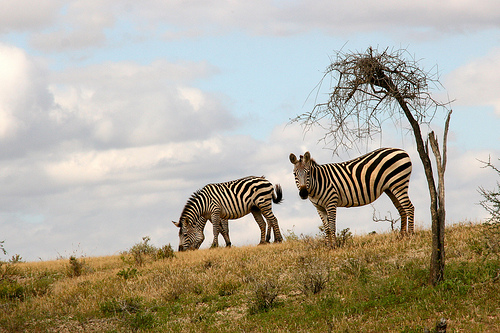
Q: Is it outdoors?
A: Yes, it is outdoors.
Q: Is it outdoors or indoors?
A: It is outdoors.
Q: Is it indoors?
A: No, it is outdoors.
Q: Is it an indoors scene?
A: No, it is outdoors.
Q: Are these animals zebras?
A: Yes, all the animals are zebras.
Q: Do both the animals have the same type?
A: Yes, all the animals are zebras.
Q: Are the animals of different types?
A: No, all the animals are zebras.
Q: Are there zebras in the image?
A: Yes, there is a zebra.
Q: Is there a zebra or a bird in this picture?
A: Yes, there is a zebra.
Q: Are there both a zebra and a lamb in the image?
A: No, there is a zebra but no lambs.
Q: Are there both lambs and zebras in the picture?
A: No, there is a zebra but no lambs.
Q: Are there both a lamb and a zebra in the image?
A: No, there is a zebra but no lambs.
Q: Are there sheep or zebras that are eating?
A: Yes, the zebra is eating.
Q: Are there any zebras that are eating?
A: Yes, there is a zebra that is eating.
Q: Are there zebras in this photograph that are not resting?
A: Yes, there is a zebra that is eating.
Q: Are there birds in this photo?
A: No, there are no birds.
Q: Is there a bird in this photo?
A: No, there are no birds.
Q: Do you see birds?
A: No, there are no birds.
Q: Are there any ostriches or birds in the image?
A: No, there are no birds or ostriches.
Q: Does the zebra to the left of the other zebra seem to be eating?
A: Yes, the zebra is eating.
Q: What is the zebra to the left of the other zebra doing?
A: The zebra is eating.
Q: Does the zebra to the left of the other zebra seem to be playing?
A: No, the zebra is eating.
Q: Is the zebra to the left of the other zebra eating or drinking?
A: The zebra is eating.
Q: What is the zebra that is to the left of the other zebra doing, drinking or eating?
A: The zebra is eating.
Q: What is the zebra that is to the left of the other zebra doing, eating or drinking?
A: The zebra is eating.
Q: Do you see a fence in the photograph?
A: No, there are no fences.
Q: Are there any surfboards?
A: No, there are no surfboards.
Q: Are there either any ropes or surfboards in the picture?
A: No, there are no surfboards or ropes.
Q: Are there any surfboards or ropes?
A: No, there are no surfboards or ropes.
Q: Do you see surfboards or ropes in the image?
A: No, there are no surfboards or ropes.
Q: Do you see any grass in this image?
A: Yes, there is grass.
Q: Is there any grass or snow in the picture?
A: Yes, there is grass.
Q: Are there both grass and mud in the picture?
A: No, there is grass but no mud.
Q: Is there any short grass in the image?
A: Yes, there is short grass.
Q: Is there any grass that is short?
A: Yes, there is grass that is short.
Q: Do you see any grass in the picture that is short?
A: Yes, there is grass that is short.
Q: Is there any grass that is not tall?
A: Yes, there is short grass.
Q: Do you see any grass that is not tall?
A: Yes, there is short grass.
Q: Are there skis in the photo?
A: No, there are no skis.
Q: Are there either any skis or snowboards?
A: No, there are no skis or snowboards.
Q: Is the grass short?
A: Yes, the grass is short.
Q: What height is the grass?
A: The grass is short.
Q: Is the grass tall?
A: No, the grass is short.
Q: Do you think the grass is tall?
A: No, the grass is short.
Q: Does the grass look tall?
A: No, the grass is short.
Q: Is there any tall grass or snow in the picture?
A: No, there is grass but it is short.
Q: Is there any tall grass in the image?
A: No, there is grass but it is short.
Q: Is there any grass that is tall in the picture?
A: No, there is grass but it is short.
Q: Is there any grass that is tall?
A: No, there is grass but it is short.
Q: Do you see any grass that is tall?
A: No, there is grass but it is short.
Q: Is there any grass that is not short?
A: No, there is grass but it is short.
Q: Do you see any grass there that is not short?
A: No, there is grass but it is short.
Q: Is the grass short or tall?
A: The grass is short.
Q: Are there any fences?
A: No, there are no fences.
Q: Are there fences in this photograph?
A: No, there are no fences.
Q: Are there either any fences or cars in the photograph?
A: No, there are no fences or cars.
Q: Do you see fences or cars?
A: No, there are no fences or cars.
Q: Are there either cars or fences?
A: No, there are no fences or cars.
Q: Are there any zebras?
A: Yes, there is a zebra.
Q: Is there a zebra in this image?
A: Yes, there is a zebra.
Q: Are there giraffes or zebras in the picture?
A: Yes, there is a zebra.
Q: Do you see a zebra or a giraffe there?
A: Yes, there is a zebra.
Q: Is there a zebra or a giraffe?
A: Yes, there is a zebra.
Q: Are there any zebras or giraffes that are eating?
A: Yes, the zebra is eating.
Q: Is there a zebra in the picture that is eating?
A: Yes, there is a zebra that is eating.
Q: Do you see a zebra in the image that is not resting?
A: Yes, there is a zebra that is eating .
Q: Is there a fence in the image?
A: No, there are no fences.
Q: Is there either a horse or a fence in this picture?
A: No, there are no fences or horses.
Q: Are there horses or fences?
A: No, there are no fences or horses.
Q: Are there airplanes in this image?
A: No, there are no airplanes.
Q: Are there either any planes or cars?
A: No, there are no planes or cars.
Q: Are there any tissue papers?
A: No, there are no tissue papers.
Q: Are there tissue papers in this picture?
A: No, there are no tissue papers.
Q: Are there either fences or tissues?
A: No, there are no tissues or fences.